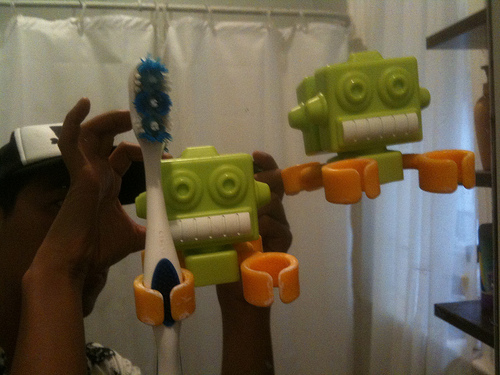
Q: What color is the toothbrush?
A: Blue and white.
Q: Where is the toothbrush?
A: In front of the hands.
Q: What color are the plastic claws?
A: Orange.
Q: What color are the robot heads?
A: Green.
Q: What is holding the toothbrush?
A: The plastic claw on the left.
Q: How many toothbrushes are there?
A: One.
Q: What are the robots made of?
A: Plastic.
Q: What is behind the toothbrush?
A: The robots.